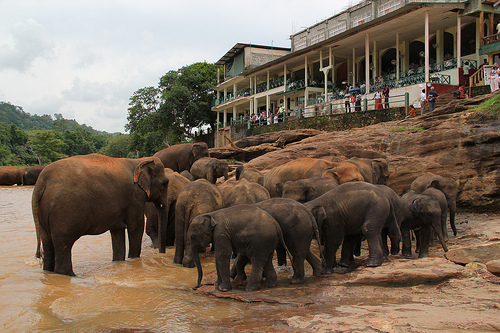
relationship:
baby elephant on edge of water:
[182, 202, 288, 292] [0, 252, 188, 331]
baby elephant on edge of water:
[255, 192, 326, 284] [0, 252, 188, 331]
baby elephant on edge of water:
[296, 180, 398, 267] [0, 252, 188, 331]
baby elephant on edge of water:
[400, 185, 450, 253] [0, 252, 188, 331]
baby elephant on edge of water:
[415, 167, 462, 234] [0, 252, 188, 331]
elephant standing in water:
[30, 153, 169, 278] [3, 184, 216, 331]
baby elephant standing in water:
[182, 202, 287, 291] [3, 184, 216, 331]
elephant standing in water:
[147, 142, 232, 182] [3, 184, 216, 331]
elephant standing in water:
[1, 165, 26, 191] [3, 184, 216, 331]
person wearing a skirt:
[371, 89, 382, 109] [368, 95, 386, 115]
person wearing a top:
[371, 89, 382, 109] [364, 80, 389, 101]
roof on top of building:
[211, 41, 290, 69] [209, 3, 499, 147]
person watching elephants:
[366, 80, 396, 130] [27, 140, 464, 279]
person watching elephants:
[332, 80, 366, 120] [27, 140, 464, 279]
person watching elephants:
[412, 71, 441, 111] [27, 140, 464, 279]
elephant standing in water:
[30, 153, 168, 277] [6, 166, 282, 329]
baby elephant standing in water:
[182, 202, 287, 291] [6, 166, 282, 329]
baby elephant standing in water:
[296, 180, 404, 276] [6, 166, 282, 329]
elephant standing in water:
[153, 179, 227, 268] [6, 166, 282, 329]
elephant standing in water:
[142, 137, 216, 169] [6, 166, 282, 329]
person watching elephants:
[326, 80, 380, 112] [26, 120, 476, 310]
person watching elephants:
[328, 70, 369, 124] [26, 120, 476, 310]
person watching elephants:
[430, 51, 484, 112] [26, 120, 476, 310]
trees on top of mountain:
[130, 62, 217, 152] [2, 97, 129, 160]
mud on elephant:
[0, 97, 499, 332] [29, 133, 181, 287]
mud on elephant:
[2, 187, 499, 331] [264, 160, 369, 186]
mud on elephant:
[2, 187, 499, 331] [20, 153, 176, 275]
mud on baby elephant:
[2, 187, 499, 331] [182, 202, 287, 291]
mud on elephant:
[2, 187, 499, 331] [304, 180, 400, 274]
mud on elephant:
[2, 187, 499, 331] [147, 141, 214, 171]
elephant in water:
[30, 153, 169, 278] [1, 181, 322, 331]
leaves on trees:
[10, 131, 27, 148] [0, 62, 215, 159]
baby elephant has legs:
[182, 202, 287, 291] [205, 245, 234, 297]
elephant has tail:
[30, 153, 168, 277] [385, 199, 404, 253]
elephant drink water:
[30, 153, 168, 277] [8, 246, 226, 320]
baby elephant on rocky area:
[182, 202, 287, 291] [137, 107, 499, 333]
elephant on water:
[30, 153, 169, 278] [8, 244, 175, 324]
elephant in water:
[30, 153, 168, 277] [12, 252, 215, 328]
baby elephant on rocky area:
[182, 202, 287, 291] [182, 274, 447, 326]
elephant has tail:
[30, 153, 168, 277] [28, 181, 49, 264]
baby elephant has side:
[182, 202, 287, 291] [39, 164, 151, 231]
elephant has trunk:
[30, 153, 168, 277] [150, 197, 175, 253]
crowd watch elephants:
[246, 72, 393, 110] [33, 119, 459, 299]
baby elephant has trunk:
[182, 202, 287, 291] [190, 246, 205, 292]